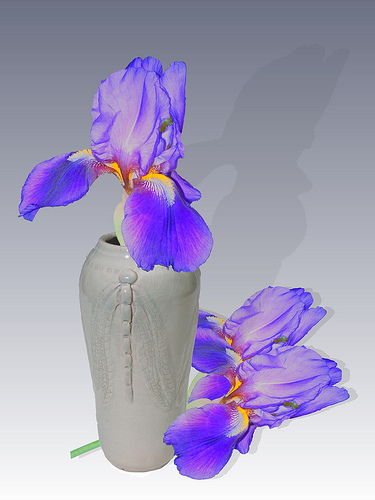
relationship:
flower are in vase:
[18, 59, 213, 273] [78, 233, 199, 474]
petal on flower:
[120, 172, 212, 274] [19, 54, 218, 274]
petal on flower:
[120, 172, 212, 274] [17, 62, 248, 275]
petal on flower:
[116, 167, 220, 275] [19, 54, 218, 274]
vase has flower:
[78, 233, 199, 474] [18, 59, 213, 273]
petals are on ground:
[172, 282, 346, 476] [1, 285, 373, 498]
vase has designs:
[78, 233, 199, 474] [96, 266, 179, 402]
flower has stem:
[177, 268, 341, 497] [68, 432, 109, 463]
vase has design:
[78, 233, 199, 474] [90, 269, 177, 409]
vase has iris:
[73, 233, 233, 416] [13, 36, 220, 220]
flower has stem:
[100, 71, 236, 267] [47, 430, 113, 463]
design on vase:
[89, 267, 177, 409] [78, 233, 199, 474]